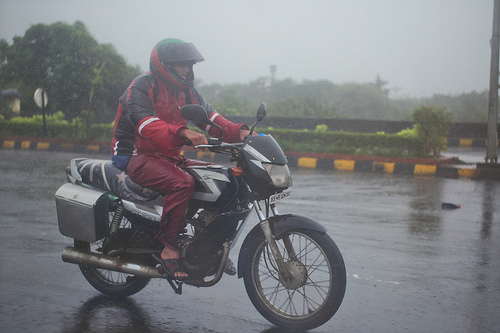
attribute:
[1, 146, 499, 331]
road — wet, asphalt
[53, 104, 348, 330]
motorcycle — black, silver, white, wet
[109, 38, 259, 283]
man — wet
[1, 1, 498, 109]
sky — raining, overcast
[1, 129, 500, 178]
curb — yellow, black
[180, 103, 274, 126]
sideview mirrors — Two side view , present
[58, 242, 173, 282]
exhaust pipe — exhaust 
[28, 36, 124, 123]
leaves — green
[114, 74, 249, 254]
suit — red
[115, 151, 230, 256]
pants — red, wet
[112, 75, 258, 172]
jacket — red, black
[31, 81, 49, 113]
sign — background.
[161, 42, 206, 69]
visor — up